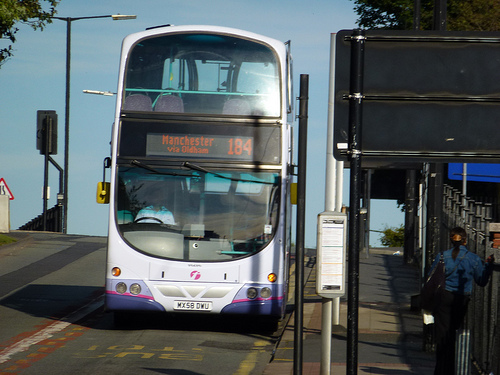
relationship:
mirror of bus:
[95, 157, 113, 204] [77, 19, 300, 326]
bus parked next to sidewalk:
[77, 19, 300, 326] [267, 235, 487, 374]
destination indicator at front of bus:
[137, 118, 283, 163] [77, 19, 300, 326]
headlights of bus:
[105, 267, 279, 312] [77, 19, 300, 326]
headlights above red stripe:
[105, 267, 279, 312] [10, 304, 105, 374]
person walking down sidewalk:
[428, 222, 488, 282] [267, 240, 452, 373]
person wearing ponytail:
[428, 222, 488, 282] [446, 235, 464, 258]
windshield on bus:
[115, 160, 280, 259] [77, 19, 300, 326]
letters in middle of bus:
[159, 131, 218, 155] [106, 13, 318, 335]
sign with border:
[0, 176, 16, 200] [0, 175, 17, 201]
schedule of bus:
[315, 212, 348, 299] [77, 19, 300, 326]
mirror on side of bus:
[94, 178, 111, 205] [77, 19, 300, 326]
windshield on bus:
[115, 160, 280, 259] [122, 21, 279, 324]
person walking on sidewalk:
[420, 230, 498, 372] [267, 240, 452, 373]